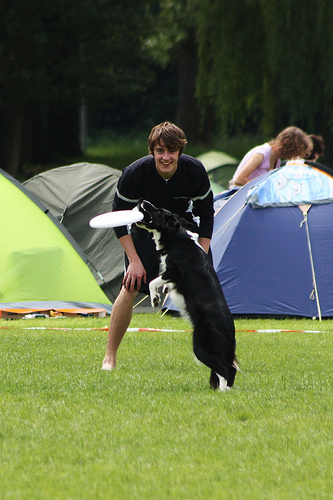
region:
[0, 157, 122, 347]
lime green tent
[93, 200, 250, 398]
dog catching a white frisbee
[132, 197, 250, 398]
black and white dog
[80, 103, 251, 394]
guy playing with the dog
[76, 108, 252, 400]
guy playing frisbee with the dog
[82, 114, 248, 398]
guy with short brown hair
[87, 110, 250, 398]
guy with long blue shirt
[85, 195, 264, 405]
dog standing on the grass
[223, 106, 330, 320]
lady near blue tent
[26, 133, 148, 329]
grey tent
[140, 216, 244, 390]
a dog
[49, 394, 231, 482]
the grass is green and short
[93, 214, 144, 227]
white frisbee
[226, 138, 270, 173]
women wearing a purple shirt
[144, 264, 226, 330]
a black and white dog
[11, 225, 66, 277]
a tent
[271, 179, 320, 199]
umbrella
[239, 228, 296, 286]
a blue tent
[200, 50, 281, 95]
green leaves on the tree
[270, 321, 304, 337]
rope on the ground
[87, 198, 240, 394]
black dog catching white frisbee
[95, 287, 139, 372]
one right Caucasian male leg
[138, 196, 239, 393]
black dog jumping on grassy field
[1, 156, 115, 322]
edge of little green tent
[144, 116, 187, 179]
dark haired man smiling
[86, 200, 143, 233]
white round frisbee midair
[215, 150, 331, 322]
one little blue tent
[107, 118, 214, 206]
man wearing dark blue long sleeved shirt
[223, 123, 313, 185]
woman wearing pink sleeveless shirt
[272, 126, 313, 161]
woman with brown curly hair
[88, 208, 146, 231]
a white Frisbee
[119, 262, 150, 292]
the hand of a man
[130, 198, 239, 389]
a dog's black and white hair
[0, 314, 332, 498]
a large section of green grass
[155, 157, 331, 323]
a large blue tent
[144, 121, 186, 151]
a boy's brown short cut hair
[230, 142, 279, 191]
a woman's purple shirt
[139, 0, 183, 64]
green tree leaves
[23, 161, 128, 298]
part of a gray tent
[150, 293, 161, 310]
the paw of a dog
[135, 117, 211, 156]
boy has brown hair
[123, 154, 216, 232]
boy has blue shirt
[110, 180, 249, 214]
white stripe on shirt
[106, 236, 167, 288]
boy has blue pants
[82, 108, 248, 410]
boy stands on grass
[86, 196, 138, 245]
dog is catching frisbee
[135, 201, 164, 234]
dog has black nose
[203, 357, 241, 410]
dog has black tail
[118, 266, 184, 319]
dog has white paws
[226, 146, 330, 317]
blue tent behind boy